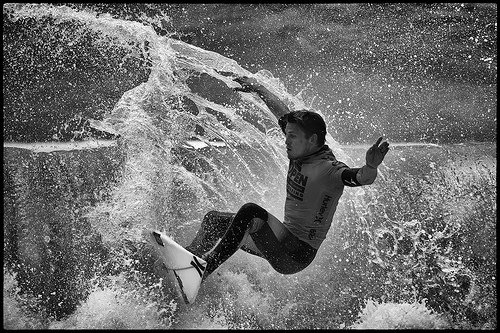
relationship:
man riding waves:
[186, 75, 390, 278] [8, 135, 278, 201]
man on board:
[186, 75, 390, 278] [148, 229, 209, 309]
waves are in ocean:
[8, 135, 278, 201] [4, 6, 376, 309]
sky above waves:
[202, 11, 489, 138] [8, 135, 278, 201]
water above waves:
[4, 6, 376, 309] [8, 135, 278, 201]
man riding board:
[186, 75, 390, 278] [148, 229, 209, 309]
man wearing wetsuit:
[186, 75, 390, 278] [185, 148, 361, 276]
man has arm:
[186, 75, 390, 278] [230, 75, 291, 135]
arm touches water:
[230, 75, 291, 135] [4, 6, 376, 309]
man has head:
[186, 75, 390, 278] [284, 109, 327, 161]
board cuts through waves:
[148, 229, 209, 309] [8, 135, 278, 201]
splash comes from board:
[100, 183, 152, 237] [148, 229, 209, 309]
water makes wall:
[4, 6, 376, 309] [20, 8, 180, 217]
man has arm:
[186, 75, 390, 278] [337, 134, 391, 187]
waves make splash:
[8, 135, 278, 201] [100, 183, 152, 237]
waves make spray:
[8, 135, 278, 201] [12, 50, 71, 107]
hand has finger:
[366, 136, 389, 168] [376, 135, 384, 148]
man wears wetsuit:
[186, 75, 390, 278] [185, 148, 361, 276]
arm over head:
[230, 75, 291, 135] [284, 109, 327, 161]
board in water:
[148, 229, 209, 309] [4, 6, 376, 309]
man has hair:
[186, 75, 390, 278] [286, 110, 326, 148]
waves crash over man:
[8, 135, 278, 201] [186, 75, 390, 278]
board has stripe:
[148, 229, 209, 309] [193, 255, 210, 270]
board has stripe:
[148, 229, 209, 309] [190, 259, 203, 279]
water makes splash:
[4, 6, 376, 309] [100, 183, 152, 237]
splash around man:
[100, 183, 152, 237] [186, 75, 390, 278]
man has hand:
[186, 75, 390, 278] [366, 136, 389, 168]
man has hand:
[186, 75, 390, 278] [232, 75, 257, 94]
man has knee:
[186, 75, 390, 278] [239, 200, 260, 226]